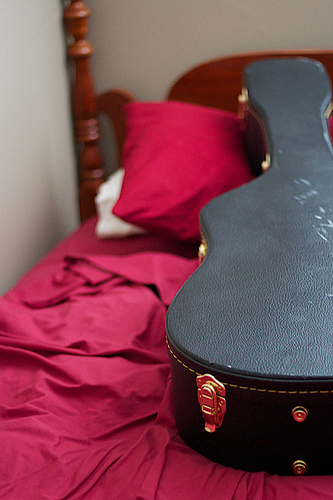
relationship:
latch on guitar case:
[195, 241, 211, 263] [161, 58, 331, 480]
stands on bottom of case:
[288, 404, 311, 477] [160, 327, 332, 476]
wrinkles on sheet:
[3, 252, 332, 498] [1, 214, 331, 499]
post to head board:
[59, 1, 108, 228] [94, 45, 331, 168]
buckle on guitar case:
[234, 90, 252, 133] [161, 58, 331, 480]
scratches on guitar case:
[291, 175, 331, 241] [161, 58, 331, 480]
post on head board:
[59, 1, 108, 228] [94, 45, 331, 168]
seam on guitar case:
[161, 332, 332, 398] [161, 58, 331, 480]